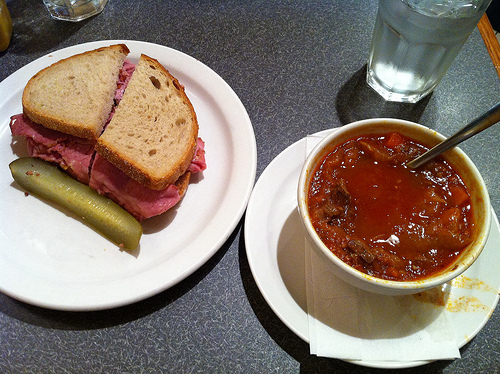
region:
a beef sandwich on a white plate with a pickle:
[9, 44, 219, 267]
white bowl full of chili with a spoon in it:
[293, 112, 495, 305]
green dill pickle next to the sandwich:
[10, 151, 143, 262]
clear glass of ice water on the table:
[363, 0, 486, 110]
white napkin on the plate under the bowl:
[308, 291, 469, 370]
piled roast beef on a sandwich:
[10, 129, 97, 181]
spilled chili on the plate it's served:
[418, 273, 498, 320]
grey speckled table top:
[219, 14, 353, 111]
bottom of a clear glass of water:
[41, 0, 111, 24]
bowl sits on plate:
[297, 114, 490, 296]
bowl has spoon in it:
[297, 117, 493, 294]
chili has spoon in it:
[308, 131, 475, 278]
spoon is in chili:
[410, 99, 499, 170]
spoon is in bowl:
[407, 103, 499, 169]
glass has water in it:
[357, 0, 491, 107]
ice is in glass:
[404, 0, 487, 28]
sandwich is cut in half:
[10, 43, 210, 220]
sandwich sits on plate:
[7, 44, 208, 216]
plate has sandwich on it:
[0, 34, 258, 314]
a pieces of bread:
[44, 46, 215, 179]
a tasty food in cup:
[308, 120, 481, 282]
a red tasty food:
[328, 107, 499, 276]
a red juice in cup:
[297, 111, 487, 316]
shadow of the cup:
[278, 272, 403, 354]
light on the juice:
[370, 220, 420, 255]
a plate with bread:
[24, 54, 261, 340]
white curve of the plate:
[64, 261, 229, 355]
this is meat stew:
[315, 131, 469, 261]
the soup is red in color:
[332, 155, 453, 263]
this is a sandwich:
[63, 47, 189, 174]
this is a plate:
[37, 239, 113, 303]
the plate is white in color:
[32, 232, 92, 298]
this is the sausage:
[135, 192, 163, 212]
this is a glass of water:
[369, 7, 463, 100]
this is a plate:
[204, 78, 233, 175]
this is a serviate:
[309, 304, 435, 350]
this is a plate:
[248, 206, 291, 301]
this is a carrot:
[450, 180, 470, 205]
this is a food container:
[300, 155, 460, 315]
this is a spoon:
[410, 100, 490, 155]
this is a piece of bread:
[50, 60, 100, 115]